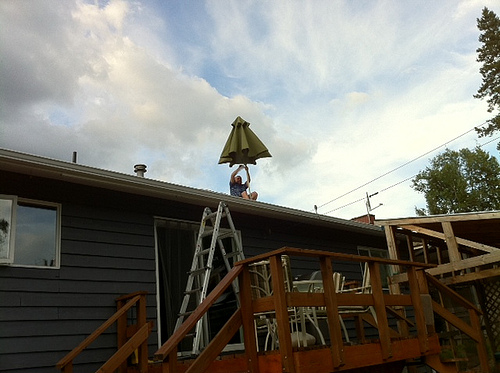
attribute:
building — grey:
[1, 142, 498, 369]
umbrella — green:
[216, 112, 277, 170]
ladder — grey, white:
[160, 196, 248, 361]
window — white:
[1, 191, 68, 276]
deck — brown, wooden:
[48, 239, 497, 368]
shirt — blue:
[228, 180, 251, 198]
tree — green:
[412, 149, 497, 207]